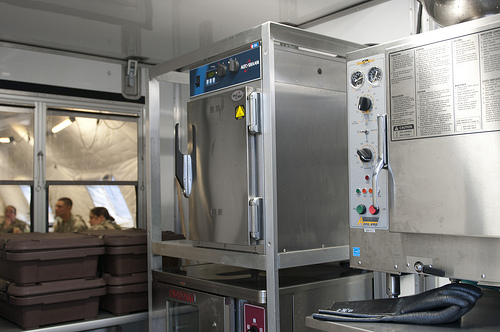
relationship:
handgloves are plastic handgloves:
[283, 255, 495, 332] [315, 281, 484, 320]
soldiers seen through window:
[0, 204, 37, 234] [1, 101, 144, 231]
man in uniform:
[49, 197, 87, 233] [50, 212, 87, 230]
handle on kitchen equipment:
[158, 143, 192, 223] [187, 209, 223, 290]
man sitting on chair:
[51, 197, 84, 230] [48, 227, 99, 293]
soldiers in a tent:
[0, 196, 126, 233] [2, 105, 140, 232]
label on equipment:
[173, 44, 263, 93] [177, 60, 343, 249]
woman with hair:
[86, 202, 120, 234] [90, 201, 118, 225]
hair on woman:
[90, 202, 115, 223] [86, 207, 124, 232]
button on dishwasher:
[367, 199, 396, 223] [324, 100, 470, 251]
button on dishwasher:
[226, 58, 242, 76] [162, 57, 335, 254]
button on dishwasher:
[223, 58, 241, 75] [143, 47, 376, 259]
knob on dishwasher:
[210, 60, 228, 80] [154, 66, 370, 276]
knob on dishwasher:
[212, 60, 229, 78] [178, 60, 330, 272]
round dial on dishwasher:
[226, 51, 253, 75] [154, 33, 389, 261]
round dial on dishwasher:
[366, 66, 384, 87] [333, 49, 495, 310]